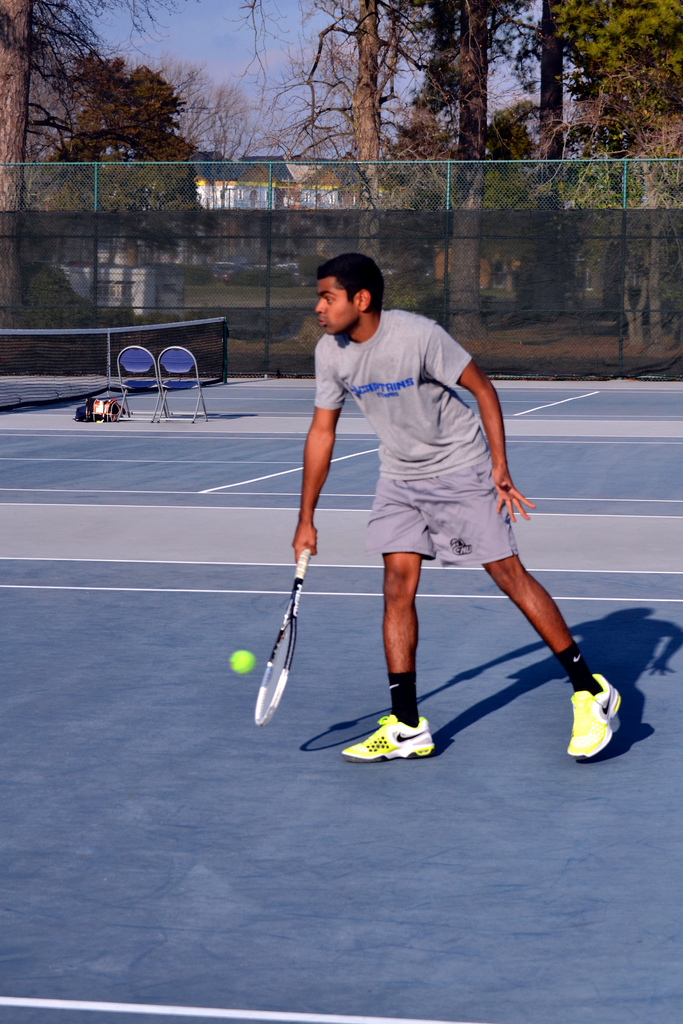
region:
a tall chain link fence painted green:
[5, 144, 676, 374]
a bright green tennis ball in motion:
[218, 642, 266, 682]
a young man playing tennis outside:
[226, 228, 627, 780]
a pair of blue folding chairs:
[110, 342, 207, 435]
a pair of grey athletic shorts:
[358, 456, 538, 574]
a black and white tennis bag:
[74, 389, 124, 429]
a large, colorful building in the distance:
[172, 126, 399, 303]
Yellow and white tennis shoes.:
[338, 678, 620, 766]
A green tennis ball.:
[224, 644, 260, 685]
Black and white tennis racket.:
[250, 548, 308, 724]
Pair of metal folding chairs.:
[119, 336, 214, 416]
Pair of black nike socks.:
[388, 645, 597, 724]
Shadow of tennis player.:
[326, 576, 680, 757]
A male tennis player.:
[276, 263, 640, 762]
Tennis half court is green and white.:
[6, 453, 676, 1017]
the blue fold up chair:
[114, 345, 161, 417]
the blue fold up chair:
[157, 342, 209, 421]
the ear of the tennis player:
[357, 289, 371, 313]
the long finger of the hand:
[511, 488, 536, 509]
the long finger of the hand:
[510, 493, 528, 520]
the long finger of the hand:
[503, 497, 514, 524]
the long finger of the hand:
[494, 494, 504, 513]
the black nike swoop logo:
[395, 726, 429, 746]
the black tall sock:
[383, 661, 419, 728]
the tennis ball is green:
[231, 650, 254, 674]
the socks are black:
[389, 640, 602, 726]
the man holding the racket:
[254, 251, 621, 764]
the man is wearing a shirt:
[252, 253, 621, 764]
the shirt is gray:
[314, 308, 489, 478]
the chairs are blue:
[117, 344, 207, 424]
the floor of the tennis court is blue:
[0, 375, 682, 1021]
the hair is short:
[318, 252, 384, 316]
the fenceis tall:
[0, 156, 681, 381]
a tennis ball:
[222, 644, 258, 680]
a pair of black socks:
[376, 635, 605, 729]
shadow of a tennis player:
[298, 601, 681, 766]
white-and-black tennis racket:
[246, 539, 320, 732]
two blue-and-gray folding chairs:
[110, 335, 224, 426]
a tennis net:
[2, 310, 237, 420]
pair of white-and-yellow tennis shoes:
[337, 668, 627, 766]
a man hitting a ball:
[219, 226, 642, 785]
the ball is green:
[214, 632, 266, 693]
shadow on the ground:
[300, 584, 679, 757]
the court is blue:
[14, 340, 679, 978]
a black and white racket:
[214, 541, 370, 733]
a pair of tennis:
[329, 636, 643, 800]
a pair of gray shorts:
[356, 446, 535, 585]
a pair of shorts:
[105, 335, 229, 434]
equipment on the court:
[63, 385, 128, 433]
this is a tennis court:
[93, 765, 523, 1022]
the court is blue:
[143, 769, 421, 961]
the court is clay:
[82, 795, 355, 937]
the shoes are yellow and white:
[377, 667, 618, 814]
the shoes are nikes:
[326, 635, 642, 771]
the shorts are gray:
[351, 432, 573, 569]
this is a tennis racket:
[231, 483, 383, 759]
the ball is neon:
[193, 649, 289, 704]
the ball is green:
[205, 628, 275, 693]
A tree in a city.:
[441, 10, 497, 345]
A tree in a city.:
[513, 9, 583, 330]